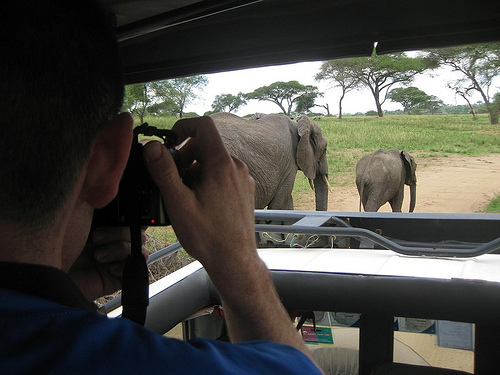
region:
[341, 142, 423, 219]
elephant walking in dirt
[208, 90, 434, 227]
two elephants walking in dirt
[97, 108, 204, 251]
camera in hand of person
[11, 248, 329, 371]
blue men's shirt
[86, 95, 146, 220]
right ear of man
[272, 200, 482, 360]
safety bars on vehicle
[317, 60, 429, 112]
trees in grass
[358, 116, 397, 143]
green grass on ground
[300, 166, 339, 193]
two horns on elephant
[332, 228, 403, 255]
black metal bar on side of window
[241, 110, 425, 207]
the elephants are walking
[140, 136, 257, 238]
camera in the hand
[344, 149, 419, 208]
the elephant is small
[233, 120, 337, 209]
the elephant is adult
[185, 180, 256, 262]
hand of the person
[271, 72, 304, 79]
the sky is white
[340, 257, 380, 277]
the kart is white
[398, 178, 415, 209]
trunk of the elephant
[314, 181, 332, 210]
trunk of the elephant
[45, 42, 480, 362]
man taking picture of elephans in the wild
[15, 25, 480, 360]
man inside of jeep on African safari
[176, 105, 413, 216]
an elephant and its baby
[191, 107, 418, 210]
African elephants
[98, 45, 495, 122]
trees in the area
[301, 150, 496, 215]
traveling on dirt road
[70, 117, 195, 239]
man is using a pro-camera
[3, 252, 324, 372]
man is wearing a blue shirt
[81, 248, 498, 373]
padding in the opening in the jeep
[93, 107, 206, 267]
man taking a photo.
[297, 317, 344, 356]
sticker in the window.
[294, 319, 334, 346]
sticker is red and green.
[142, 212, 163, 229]
red light on the camera.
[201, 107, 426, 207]
two elephants are walking.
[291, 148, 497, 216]
the dirt is brown.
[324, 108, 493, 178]
the grass is green.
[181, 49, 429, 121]
the sky is white.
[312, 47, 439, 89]
the leaves are green.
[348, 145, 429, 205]
a young elephant walking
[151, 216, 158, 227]
a red light on a photo camera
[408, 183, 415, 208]
the trunk of an elephant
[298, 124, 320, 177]
the ear of an elephant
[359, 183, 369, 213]
the tail of an elephant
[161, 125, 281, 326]
a hand of a man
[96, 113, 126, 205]
the ear of a man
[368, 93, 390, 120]
the trunk of a tree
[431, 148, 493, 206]
a path in the park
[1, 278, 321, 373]
shirt worn by human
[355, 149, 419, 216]
elephant in front of vehicle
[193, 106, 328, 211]
elephant in front of vehicle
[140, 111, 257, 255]
hand belongs to human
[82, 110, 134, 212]
ear belongs to human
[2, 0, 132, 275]
head belongs to human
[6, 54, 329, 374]
man wearing a blue shirt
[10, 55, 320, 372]
man wearing blue shirt taking a picture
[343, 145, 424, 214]
a baby elephant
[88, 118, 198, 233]
a black camera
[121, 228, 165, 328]
strap hanging from the black camera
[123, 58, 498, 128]
a row of trees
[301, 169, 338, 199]
tusks on a large elephant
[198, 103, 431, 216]
elephants on a dirt road